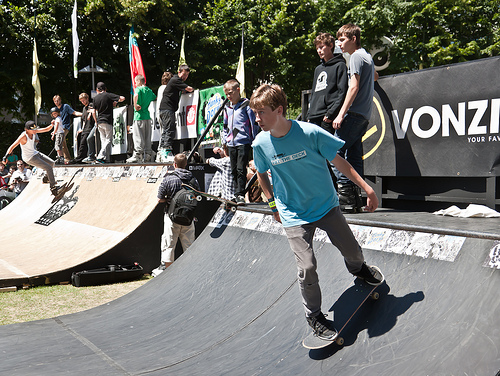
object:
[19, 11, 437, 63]
background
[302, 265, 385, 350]
skateboard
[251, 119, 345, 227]
shirt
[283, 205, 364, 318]
pants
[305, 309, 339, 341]
shoes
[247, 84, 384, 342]
boy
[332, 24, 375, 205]
boys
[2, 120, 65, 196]
skateboarders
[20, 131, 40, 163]
tank top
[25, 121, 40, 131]
cap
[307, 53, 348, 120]
pullover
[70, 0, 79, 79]
flag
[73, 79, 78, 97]
pole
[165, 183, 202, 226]
backpack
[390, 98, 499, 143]
advertisement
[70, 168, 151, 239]
halfpipe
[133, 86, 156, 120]
tshirt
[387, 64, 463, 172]
wall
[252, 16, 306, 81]
tree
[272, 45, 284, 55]
leaves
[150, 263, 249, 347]
ramp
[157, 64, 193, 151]
people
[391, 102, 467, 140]
logo